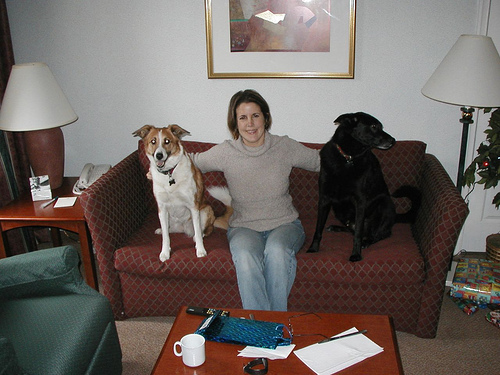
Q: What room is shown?
A: It is a living room.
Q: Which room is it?
A: It is a living room.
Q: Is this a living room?
A: Yes, it is a living room.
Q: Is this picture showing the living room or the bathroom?
A: It is showing the living room.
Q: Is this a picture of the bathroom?
A: No, the picture is showing the living room.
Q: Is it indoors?
A: Yes, it is indoors.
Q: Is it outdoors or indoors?
A: It is indoors.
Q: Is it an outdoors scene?
A: No, it is indoors.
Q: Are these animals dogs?
A: Yes, all the animals are dogs.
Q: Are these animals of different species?
A: No, all the animals are dogs.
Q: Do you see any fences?
A: No, there are no fences.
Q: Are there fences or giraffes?
A: No, there are no fences or giraffes.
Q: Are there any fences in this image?
A: No, there are no fences.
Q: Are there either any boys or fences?
A: No, there are no fences or boys.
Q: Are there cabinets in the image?
A: No, there are no cabinets.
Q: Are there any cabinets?
A: No, there are no cabinets.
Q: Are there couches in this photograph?
A: Yes, there is a couch.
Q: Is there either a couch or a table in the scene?
A: Yes, there is a couch.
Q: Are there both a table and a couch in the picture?
A: Yes, there are both a couch and a table.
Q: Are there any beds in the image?
A: No, there are no beds.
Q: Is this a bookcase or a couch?
A: This is a couch.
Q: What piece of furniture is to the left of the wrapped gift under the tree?
A: The piece of furniture is a couch.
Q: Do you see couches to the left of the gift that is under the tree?
A: Yes, there is a couch to the left of the gift.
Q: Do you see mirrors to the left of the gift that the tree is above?
A: No, there is a couch to the left of the gift.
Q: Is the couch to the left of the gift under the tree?
A: Yes, the couch is to the left of the gift.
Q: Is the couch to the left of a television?
A: No, the couch is to the left of the gift.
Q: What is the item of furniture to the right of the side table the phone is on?
A: The piece of furniture is a couch.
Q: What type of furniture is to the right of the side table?
A: The piece of furniture is a couch.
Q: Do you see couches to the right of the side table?
A: Yes, there is a couch to the right of the side table.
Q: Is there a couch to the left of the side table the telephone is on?
A: No, the couch is to the right of the side table.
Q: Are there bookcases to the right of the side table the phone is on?
A: No, there is a couch to the right of the side table.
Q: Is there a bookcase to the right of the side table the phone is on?
A: No, there is a couch to the right of the side table.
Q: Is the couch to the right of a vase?
A: No, the couch is to the right of the side table.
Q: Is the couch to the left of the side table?
A: No, the couch is to the right of the side table.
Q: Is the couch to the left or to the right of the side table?
A: The couch is to the right of the side table.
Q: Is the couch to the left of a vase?
A: No, the couch is to the left of a gift.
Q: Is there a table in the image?
A: Yes, there is a table.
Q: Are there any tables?
A: Yes, there is a table.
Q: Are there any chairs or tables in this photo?
A: Yes, there is a table.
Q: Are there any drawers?
A: No, there are no drawers.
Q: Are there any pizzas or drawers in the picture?
A: No, there are no drawers or pizzas.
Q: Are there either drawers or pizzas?
A: No, there are no drawers or pizzas.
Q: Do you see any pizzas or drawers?
A: No, there are no drawers or pizzas.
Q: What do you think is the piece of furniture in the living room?
A: The piece of furniture is a table.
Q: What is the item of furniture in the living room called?
A: The piece of furniture is a table.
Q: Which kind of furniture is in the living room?
A: The piece of furniture is a table.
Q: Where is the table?
A: The table is in the living room.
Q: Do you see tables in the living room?
A: Yes, there is a table in the living room.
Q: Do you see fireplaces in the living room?
A: No, there is a table in the living room.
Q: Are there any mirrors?
A: No, there are no mirrors.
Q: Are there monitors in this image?
A: No, there are no monitors.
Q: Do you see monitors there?
A: No, there are no monitors.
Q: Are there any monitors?
A: No, there are no monitors.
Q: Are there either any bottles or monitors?
A: No, there are no monitors or bottles.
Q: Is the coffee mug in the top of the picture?
A: No, the coffee mug is in the bottom of the image.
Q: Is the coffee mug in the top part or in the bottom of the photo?
A: The coffee mug is in the bottom of the image.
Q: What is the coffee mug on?
A: The coffee mug is on the table.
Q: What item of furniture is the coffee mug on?
A: The coffee mug is on the table.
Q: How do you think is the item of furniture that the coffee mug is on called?
A: The piece of furniture is a table.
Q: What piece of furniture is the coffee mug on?
A: The coffee mug is on the table.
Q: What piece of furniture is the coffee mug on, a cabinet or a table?
A: The coffee mug is on a table.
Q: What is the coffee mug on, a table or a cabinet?
A: The coffee mug is on a table.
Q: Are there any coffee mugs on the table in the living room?
A: Yes, there is a coffee mug on the table.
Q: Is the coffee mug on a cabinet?
A: No, the coffee mug is on the table.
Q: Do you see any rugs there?
A: No, there are no rugs.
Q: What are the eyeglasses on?
A: The eyeglasses are on the table.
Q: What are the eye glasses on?
A: The eyeglasses are on the table.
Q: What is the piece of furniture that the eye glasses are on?
A: The piece of furniture is a table.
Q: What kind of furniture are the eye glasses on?
A: The eye glasses are on the table.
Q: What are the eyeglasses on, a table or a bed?
A: The eyeglasses are on a table.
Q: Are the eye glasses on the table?
A: Yes, the eye glasses are on the table.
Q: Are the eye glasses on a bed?
A: No, the eye glasses are on the table.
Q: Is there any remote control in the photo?
A: Yes, there is a remote control.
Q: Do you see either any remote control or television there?
A: Yes, there is a remote control.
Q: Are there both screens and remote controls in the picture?
A: No, there is a remote control but no screens.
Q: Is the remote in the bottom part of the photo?
A: Yes, the remote is in the bottom of the image.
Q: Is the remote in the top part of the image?
A: No, the remote is in the bottom of the image.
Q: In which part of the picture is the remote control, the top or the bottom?
A: The remote control is in the bottom of the image.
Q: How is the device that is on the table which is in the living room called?
A: The device is a remote control.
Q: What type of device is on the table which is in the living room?
A: The device is a remote control.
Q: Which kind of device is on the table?
A: The device is a remote control.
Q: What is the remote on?
A: The remote is on the table.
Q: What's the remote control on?
A: The remote is on the table.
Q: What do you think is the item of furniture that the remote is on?
A: The piece of furniture is a table.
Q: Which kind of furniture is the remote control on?
A: The remote is on the table.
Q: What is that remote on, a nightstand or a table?
A: The remote is on a table.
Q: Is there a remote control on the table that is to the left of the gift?
A: Yes, there is a remote control on the table.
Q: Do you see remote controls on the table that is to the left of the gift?
A: Yes, there is a remote control on the table.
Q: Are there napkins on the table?
A: No, there is a remote control on the table.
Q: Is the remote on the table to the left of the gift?
A: Yes, the remote is on the table.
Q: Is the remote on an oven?
A: No, the remote is on the table.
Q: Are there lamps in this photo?
A: Yes, there is a lamp.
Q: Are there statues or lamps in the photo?
A: Yes, there is a lamp.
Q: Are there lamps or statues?
A: Yes, there is a lamp.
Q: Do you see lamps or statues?
A: Yes, there is a lamp.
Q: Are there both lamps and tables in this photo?
A: Yes, there are both a lamp and a table.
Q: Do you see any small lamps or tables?
A: Yes, there is a small lamp.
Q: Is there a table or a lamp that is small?
A: Yes, the lamp is small.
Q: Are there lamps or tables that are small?
A: Yes, the lamp is small.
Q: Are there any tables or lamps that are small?
A: Yes, the lamp is small.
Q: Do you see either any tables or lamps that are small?
A: Yes, the lamp is small.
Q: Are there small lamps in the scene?
A: Yes, there is a small lamp.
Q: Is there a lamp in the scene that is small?
A: Yes, there is a lamp that is small.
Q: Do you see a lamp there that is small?
A: Yes, there is a lamp that is small.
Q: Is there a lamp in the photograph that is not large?
A: Yes, there is a small lamp.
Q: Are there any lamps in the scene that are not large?
A: Yes, there is a small lamp.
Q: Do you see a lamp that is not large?
A: Yes, there is a small lamp.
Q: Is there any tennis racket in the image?
A: No, there are no rackets.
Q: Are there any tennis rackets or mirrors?
A: No, there are no tennis rackets or mirrors.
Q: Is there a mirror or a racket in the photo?
A: No, there are no rackets or mirrors.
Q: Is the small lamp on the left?
A: Yes, the lamp is on the left of the image.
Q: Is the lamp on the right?
A: No, the lamp is on the left of the image.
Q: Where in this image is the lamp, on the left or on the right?
A: The lamp is on the left of the image.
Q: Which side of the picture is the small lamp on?
A: The lamp is on the left of the image.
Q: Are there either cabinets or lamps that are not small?
A: No, there is a lamp but it is small.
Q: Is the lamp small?
A: Yes, the lamp is small.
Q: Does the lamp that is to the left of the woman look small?
A: Yes, the lamp is small.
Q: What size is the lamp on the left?
A: The lamp is small.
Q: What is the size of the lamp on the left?
A: The lamp is small.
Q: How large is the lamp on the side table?
A: The lamp is small.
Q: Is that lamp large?
A: No, the lamp is small.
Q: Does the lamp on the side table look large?
A: No, the lamp is small.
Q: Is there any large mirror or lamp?
A: No, there is a lamp but it is small.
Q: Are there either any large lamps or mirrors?
A: No, there is a lamp but it is small.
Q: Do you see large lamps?
A: No, there is a lamp but it is small.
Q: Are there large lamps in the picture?
A: No, there is a lamp but it is small.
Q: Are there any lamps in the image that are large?
A: No, there is a lamp but it is small.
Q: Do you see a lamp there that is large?
A: No, there is a lamp but it is small.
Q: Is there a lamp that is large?
A: No, there is a lamp but it is small.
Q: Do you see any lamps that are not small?
A: No, there is a lamp but it is small.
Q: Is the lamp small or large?
A: The lamp is small.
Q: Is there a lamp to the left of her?
A: Yes, there is a lamp to the left of the woman.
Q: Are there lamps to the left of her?
A: Yes, there is a lamp to the left of the woman.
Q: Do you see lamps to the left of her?
A: Yes, there is a lamp to the left of the woman.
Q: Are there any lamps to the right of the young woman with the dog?
A: No, the lamp is to the left of the woman.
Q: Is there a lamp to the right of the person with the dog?
A: No, the lamp is to the left of the woman.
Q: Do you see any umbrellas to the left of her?
A: No, there is a lamp to the left of the woman.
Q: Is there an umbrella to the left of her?
A: No, there is a lamp to the left of the woman.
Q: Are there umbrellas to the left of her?
A: No, there is a lamp to the left of the woman.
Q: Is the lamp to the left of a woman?
A: Yes, the lamp is to the left of a woman.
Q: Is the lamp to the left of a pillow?
A: No, the lamp is to the left of a woman.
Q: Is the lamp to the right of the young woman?
A: No, the lamp is to the left of the woman.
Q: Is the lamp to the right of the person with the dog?
A: No, the lamp is to the left of the woman.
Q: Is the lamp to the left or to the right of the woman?
A: The lamp is to the left of the woman.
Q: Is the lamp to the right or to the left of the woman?
A: The lamp is to the left of the woman.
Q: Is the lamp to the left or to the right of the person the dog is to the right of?
A: The lamp is to the left of the woman.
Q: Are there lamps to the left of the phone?
A: Yes, there is a lamp to the left of the phone.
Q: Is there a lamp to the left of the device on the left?
A: Yes, there is a lamp to the left of the phone.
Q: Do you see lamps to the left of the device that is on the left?
A: Yes, there is a lamp to the left of the phone.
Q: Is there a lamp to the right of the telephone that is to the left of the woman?
A: No, the lamp is to the left of the phone.